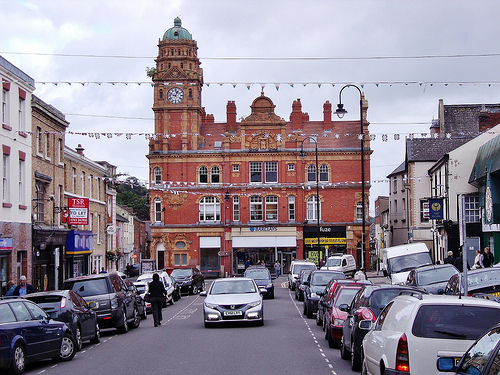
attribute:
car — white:
[358, 288, 497, 373]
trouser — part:
[136, 303, 169, 322]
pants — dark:
[152, 296, 164, 322]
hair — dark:
[152, 269, 159, 284]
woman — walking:
[140, 267, 170, 331]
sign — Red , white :
[66, 195, 89, 227]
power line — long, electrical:
[3, 48, 495, 69]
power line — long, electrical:
[1, 73, 498, 85]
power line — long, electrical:
[2, 124, 497, 152]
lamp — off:
[333, 103, 346, 120]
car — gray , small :
[198, 265, 268, 335]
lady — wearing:
[131, 265, 177, 336]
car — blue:
[342, 284, 473, 374]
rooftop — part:
[395, 122, 494, 166]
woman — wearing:
[148, 271, 170, 328]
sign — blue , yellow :
[430, 200, 442, 220]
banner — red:
[55, 190, 96, 232]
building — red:
[149, 122, 326, 229]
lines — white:
[301, 340, 333, 363]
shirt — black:
[146, 280, 165, 299]